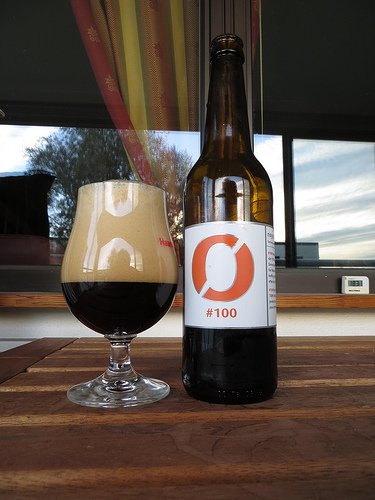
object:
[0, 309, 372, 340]
wall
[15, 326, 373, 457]
table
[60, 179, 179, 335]
coke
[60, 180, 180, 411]
wine glass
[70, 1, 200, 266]
curtain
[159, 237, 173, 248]
writing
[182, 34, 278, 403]
glass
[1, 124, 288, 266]
window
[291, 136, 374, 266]
window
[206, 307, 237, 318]
number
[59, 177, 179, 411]
glass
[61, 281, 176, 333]
beer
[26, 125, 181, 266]
tree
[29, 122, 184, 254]
reflection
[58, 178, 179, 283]
foam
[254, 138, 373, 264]
jet trails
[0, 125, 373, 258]
sky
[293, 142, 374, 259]
cloudy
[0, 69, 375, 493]
restuarant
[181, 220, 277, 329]
label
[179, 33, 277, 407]
beer bottle